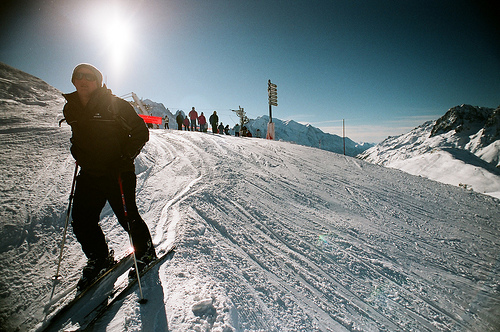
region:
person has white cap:
[65, 56, 96, 91]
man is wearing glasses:
[77, 70, 95, 82]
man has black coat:
[66, 90, 145, 180]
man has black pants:
[61, 177, 138, 283]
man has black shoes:
[75, 238, 157, 293]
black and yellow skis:
[50, 238, 172, 327]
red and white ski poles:
[54, 160, 152, 300]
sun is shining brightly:
[77, 8, 153, 81]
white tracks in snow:
[152, 131, 207, 248]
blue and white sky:
[308, 70, 418, 140]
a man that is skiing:
[34, 62, 216, 326]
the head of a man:
[60, 62, 105, 97]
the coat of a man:
[45, 91, 145, 166]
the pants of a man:
[57, 163, 155, 253]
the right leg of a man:
[67, 171, 112, 262]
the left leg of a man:
[117, 188, 168, 252]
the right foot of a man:
[75, 251, 117, 282]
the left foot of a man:
[127, 255, 164, 279]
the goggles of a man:
[68, 65, 93, 80]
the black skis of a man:
[42, 251, 136, 325]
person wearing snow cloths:
[58, 63, 159, 284]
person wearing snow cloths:
[208, 110, 220, 135]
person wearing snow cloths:
[198, 110, 208, 130]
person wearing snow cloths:
[188, 106, 197, 128]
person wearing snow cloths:
[174, 110, 184, 128]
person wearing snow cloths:
[182, 113, 192, 127]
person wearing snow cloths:
[216, 121, 224, 133]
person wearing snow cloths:
[223, 123, 229, 134]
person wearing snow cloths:
[232, 119, 241, 134]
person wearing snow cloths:
[161, 114, 171, 129]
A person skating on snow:
[42, 62, 186, 297]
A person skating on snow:
[208, 104, 218, 132]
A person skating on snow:
[194, 106, 212, 137]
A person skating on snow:
[170, 102, 187, 132]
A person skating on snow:
[155, 106, 172, 127]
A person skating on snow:
[237, 116, 254, 137]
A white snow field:
[211, 190, 346, 311]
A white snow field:
[341, 164, 458, 325]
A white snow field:
[154, 250, 249, 328]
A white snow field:
[150, 122, 241, 207]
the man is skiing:
[25, 42, 197, 319]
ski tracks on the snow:
[162, 132, 228, 285]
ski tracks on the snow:
[136, 136, 214, 254]